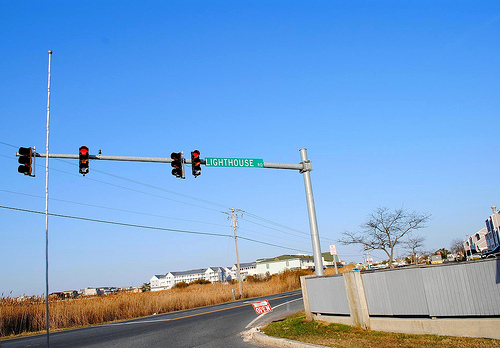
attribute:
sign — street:
[202, 145, 273, 185]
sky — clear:
[90, 253, 125, 286]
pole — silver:
[286, 147, 335, 262]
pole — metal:
[289, 146, 327, 276]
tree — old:
[336, 202, 432, 264]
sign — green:
[204, 157, 263, 167]